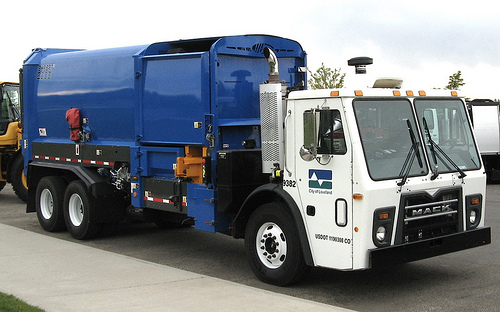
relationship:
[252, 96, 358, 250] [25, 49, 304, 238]
door on truck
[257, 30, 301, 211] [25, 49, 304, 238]
pipe on truck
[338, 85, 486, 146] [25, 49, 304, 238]
windshield on truck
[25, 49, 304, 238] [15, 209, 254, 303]
truck on road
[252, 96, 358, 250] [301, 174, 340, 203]
door has logo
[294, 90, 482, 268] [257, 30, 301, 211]
cab has muffler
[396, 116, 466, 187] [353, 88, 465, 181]
wipers not moving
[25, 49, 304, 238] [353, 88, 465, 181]
truck has window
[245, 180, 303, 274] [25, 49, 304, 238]
tire on truck